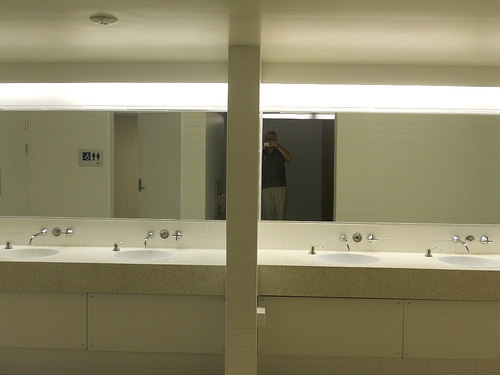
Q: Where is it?
A: This is at the restroom.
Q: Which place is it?
A: It is a restroom.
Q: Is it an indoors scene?
A: Yes, it is indoors.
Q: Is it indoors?
A: Yes, it is indoors.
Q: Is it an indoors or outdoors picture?
A: It is indoors.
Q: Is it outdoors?
A: No, it is indoors.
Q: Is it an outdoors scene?
A: No, it is indoors.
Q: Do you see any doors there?
A: Yes, there is a door.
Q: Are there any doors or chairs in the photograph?
A: Yes, there is a door.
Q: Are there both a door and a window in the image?
A: No, there is a door but no windows.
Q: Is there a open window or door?
A: Yes, there is an open door.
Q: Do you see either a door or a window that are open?
A: Yes, the door is open.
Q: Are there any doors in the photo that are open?
A: Yes, there is an open door.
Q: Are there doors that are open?
A: Yes, there is a door that is open.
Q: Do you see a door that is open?
A: Yes, there is a door that is open.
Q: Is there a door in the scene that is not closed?
A: Yes, there is a open door.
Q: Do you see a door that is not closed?
A: Yes, there is a open door.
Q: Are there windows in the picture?
A: No, there are no windows.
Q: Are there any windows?
A: No, there are no windows.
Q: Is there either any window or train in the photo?
A: No, there are no windows or trains.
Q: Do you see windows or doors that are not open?
A: No, there is a door but it is open.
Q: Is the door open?
A: Yes, the door is open.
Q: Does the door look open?
A: Yes, the door is open.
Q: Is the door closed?
A: No, the door is open.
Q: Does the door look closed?
A: No, the door is open.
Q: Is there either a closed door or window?
A: No, there is a door but it is open.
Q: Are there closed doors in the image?
A: No, there is a door but it is open.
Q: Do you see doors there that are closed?
A: No, there is a door but it is open.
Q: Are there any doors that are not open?
A: No, there is a door but it is open.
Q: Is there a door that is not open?
A: No, there is a door but it is open.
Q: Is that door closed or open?
A: The door is open.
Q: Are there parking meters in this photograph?
A: No, there are no parking meters.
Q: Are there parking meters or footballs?
A: No, there are no parking meters or footballs.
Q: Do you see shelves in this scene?
A: No, there are no shelves.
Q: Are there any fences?
A: No, there are no fences.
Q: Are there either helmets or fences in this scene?
A: No, there are no fences or helmets.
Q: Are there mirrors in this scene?
A: Yes, there is a mirror.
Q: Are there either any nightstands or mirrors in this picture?
A: Yes, there is a mirror.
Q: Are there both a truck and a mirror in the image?
A: No, there is a mirror but no trucks.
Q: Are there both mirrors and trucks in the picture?
A: No, there is a mirror but no trucks.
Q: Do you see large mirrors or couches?
A: Yes, there is a large mirror.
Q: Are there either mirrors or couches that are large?
A: Yes, the mirror is large.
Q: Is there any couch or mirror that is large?
A: Yes, the mirror is large.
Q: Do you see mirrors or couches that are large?
A: Yes, the mirror is large.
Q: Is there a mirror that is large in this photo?
A: Yes, there is a large mirror.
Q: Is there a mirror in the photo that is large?
A: Yes, there is a mirror that is large.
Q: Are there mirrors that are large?
A: Yes, there is a mirror that is large.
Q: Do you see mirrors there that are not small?
A: Yes, there is a large mirror.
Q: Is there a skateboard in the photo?
A: No, there are no skateboards.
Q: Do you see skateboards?
A: No, there are no skateboards.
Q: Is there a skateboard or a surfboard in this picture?
A: No, there are no skateboards or surfboards.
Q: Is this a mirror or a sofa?
A: This is a mirror.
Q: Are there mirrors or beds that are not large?
A: No, there is a mirror but it is large.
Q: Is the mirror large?
A: Yes, the mirror is large.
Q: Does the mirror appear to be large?
A: Yes, the mirror is large.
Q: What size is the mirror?
A: The mirror is large.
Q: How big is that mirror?
A: The mirror is large.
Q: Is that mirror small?
A: No, the mirror is large.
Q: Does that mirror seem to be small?
A: No, the mirror is large.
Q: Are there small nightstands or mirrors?
A: No, there is a mirror but it is large.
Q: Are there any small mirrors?
A: No, there is a mirror but it is large.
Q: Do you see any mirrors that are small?
A: No, there is a mirror but it is large.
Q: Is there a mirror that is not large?
A: No, there is a mirror but it is large.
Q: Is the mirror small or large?
A: The mirror is large.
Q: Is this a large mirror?
A: Yes, this is a large mirror.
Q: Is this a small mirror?
A: No, this is a large mirror.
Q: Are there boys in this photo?
A: No, there are no boys.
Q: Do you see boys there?
A: No, there are no boys.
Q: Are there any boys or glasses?
A: No, there are no boys or glasses.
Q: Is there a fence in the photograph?
A: No, there are no fences.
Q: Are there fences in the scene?
A: No, there are no fences.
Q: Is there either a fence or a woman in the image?
A: No, there are no fences or women.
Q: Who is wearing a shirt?
A: The man is wearing a shirt.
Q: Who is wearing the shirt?
A: The man is wearing a shirt.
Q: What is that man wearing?
A: The man is wearing a shirt.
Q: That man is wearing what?
A: The man is wearing a shirt.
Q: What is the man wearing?
A: The man is wearing a shirt.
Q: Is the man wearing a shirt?
A: Yes, the man is wearing a shirt.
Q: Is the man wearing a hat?
A: No, the man is wearing a shirt.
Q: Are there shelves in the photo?
A: No, there are no shelves.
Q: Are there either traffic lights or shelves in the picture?
A: No, there are no shelves or traffic lights.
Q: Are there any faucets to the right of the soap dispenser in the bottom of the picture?
A: Yes, there is a faucet to the right of the soap dispenser.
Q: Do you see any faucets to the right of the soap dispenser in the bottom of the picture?
A: Yes, there is a faucet to the right of the soap dispenser.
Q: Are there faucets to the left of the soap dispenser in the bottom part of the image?
A: No, the faucet is to the right of the soap dispenser.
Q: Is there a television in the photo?
A: No, there are no televisions.